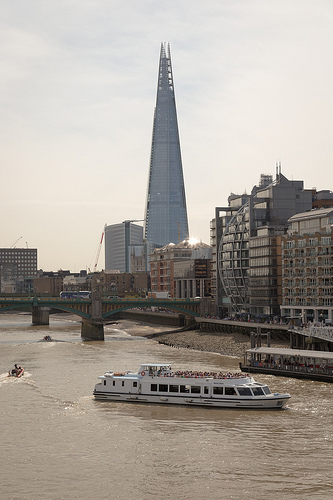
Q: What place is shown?
A: It is a city.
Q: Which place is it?
A: It is a city.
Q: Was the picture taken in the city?
A: Yes, it was taken in the city.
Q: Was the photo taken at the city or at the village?
A: It was taken at the city.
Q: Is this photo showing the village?
A: No, the picture is showing the city.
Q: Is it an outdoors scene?
A: Yes, it is outdoors.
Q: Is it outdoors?
A: Yes, it is outdoors.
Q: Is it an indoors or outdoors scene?
A: It is outdoors.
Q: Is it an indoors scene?
A: No, it is outdoors.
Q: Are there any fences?
A: No, there are no fences.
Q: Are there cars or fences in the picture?
A: No, there are no fences or cars.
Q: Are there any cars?
A: No, there are no cars.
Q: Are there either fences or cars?
A: No, there are no cars or fences.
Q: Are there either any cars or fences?
A: No, there are no cars or fences.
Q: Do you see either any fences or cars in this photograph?
A: No, there are no cars or fences.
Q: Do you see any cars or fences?
A: No, there are no cars or fences.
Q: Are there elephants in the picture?
A: No, there are no elephants.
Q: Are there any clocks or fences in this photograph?
A: No, there are no fences or clocks.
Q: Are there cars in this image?
A: No, there are no cars.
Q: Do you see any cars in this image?
A: No, there are no cars.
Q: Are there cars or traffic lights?
A: No, there are no cars or traffic lights.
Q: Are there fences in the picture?
A: No, there are no fences.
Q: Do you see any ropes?
A: No, there are no ropes.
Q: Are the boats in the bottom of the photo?
A: Yes, the boats are in the bottom of the image.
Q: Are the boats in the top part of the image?
A: No, the boats are in the bottom of the image.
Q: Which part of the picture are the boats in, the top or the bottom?
A: The boats are in the bottom of the image.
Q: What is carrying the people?
A: The boats are carrying the people.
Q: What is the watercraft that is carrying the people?
A: The watercraft is boats.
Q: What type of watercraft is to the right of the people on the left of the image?
A: The watercraft is boats.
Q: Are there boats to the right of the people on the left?
A: Yes, there are boats to the right of the people.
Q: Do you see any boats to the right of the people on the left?
A: Yes, there are boats to the right of the people.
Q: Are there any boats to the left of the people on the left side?
A: No, the boats are to the right of the people.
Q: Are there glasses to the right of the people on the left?
A: No, there are boats to the right of the people.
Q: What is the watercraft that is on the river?
A: The watercraft is boats.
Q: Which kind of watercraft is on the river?
A: The watercraft is boats.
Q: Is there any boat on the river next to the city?
A: Yes, there are boats on the river.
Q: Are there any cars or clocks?
A: No, there are no cars or clocks.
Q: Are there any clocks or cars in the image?
A: No, there are no cars or clocks.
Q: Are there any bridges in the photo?
A: Yes, there is a bridge.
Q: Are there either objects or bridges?
A: Yes, there is a bridge.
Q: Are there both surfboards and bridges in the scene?
A: No, there is a bridge but no surfboards.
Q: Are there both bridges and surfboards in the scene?
A: No, there is a bridge but no surfboards.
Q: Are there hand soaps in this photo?
A: No, there are no hand soaps.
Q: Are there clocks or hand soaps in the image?
A: No, there are no hand soaps or clocks.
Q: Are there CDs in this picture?
A: No, there are no cds.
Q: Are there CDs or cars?
A: No, there are no CDs or cars.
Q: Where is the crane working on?
A: The crane is working on the building.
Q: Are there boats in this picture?
A: Yes, there is a boat.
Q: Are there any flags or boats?
A: Yes, there is a boat.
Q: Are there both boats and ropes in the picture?
A: No, there is a boat but no ropes.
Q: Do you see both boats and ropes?
A: No, there is a boat but no ropes.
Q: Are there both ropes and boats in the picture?
A: No, there is a boat but no ropes.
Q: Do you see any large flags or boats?
A: Yes, there is a large boat.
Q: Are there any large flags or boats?
A: Yes, there is a large boat.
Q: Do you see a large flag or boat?
A: Yes, there is a large boat.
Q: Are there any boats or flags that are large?
A: Yes, the boat is large.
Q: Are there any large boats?
A: Yes, there is a large boat.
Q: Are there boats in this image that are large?
A: Yes, there is a boat that is large.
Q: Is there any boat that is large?
A: Yes, there is a boat that is large.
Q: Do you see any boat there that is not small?
A: Yes, there is a large boat.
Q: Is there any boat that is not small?
A: Yes, there is a large boat.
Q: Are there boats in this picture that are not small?
A: Yes, there is a large boat.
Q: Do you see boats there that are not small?
A: Yes, there is a large boat.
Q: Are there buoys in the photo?
A: No, there are no buoys.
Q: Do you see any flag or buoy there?
A: No, there are no buoys or flags.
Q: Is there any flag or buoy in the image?
A: No, there are no buoys or flags.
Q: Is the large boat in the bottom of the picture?
A: Yes, the boat is in the bottom of the image.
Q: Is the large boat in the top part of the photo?
A: No, the boat is in the bottom of the image.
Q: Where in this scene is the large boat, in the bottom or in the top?
A: The boat is in the bottom of the image.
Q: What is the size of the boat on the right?
A: The boat is large.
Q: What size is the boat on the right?
A: The boat is large.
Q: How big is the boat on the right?
A: The boat is large.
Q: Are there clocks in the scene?
A: No, there are no clocks.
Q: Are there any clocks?
A: No, there are no clocks.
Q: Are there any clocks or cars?
A: No, there are no clocks or cars.